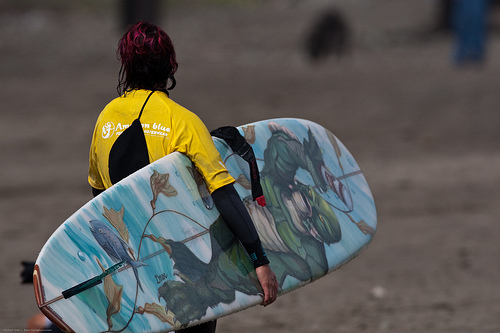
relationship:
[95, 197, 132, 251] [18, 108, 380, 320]
leaf on surfboard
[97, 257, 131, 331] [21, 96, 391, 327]
leaf on surfboard